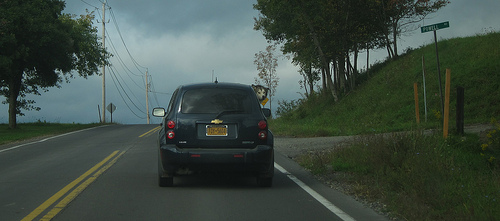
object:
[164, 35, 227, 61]
cloud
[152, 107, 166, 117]
mirror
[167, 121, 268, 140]
lights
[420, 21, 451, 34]
sign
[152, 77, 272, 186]
car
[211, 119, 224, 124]
logo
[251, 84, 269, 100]
dog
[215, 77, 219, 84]
antennae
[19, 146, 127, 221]
line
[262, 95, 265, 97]
nose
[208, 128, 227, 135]
license plate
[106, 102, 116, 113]
sign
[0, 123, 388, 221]
road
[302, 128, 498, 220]
grass